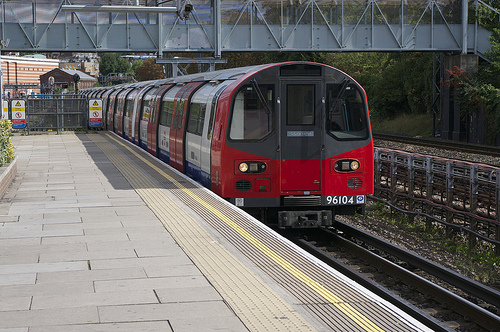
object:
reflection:
[104, 86, 228, 140]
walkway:
[0, 0, 500, 58]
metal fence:
[25, 93, 89, 135]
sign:
[88, 99, 102, 131]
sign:
[11, 99, 26, 128]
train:
[63, 60, 375, 230]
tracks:
[280, 133, 499, 332]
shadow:
[74, 123, 200, 191]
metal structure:
[0, 0, 500, 66]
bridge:
[0, 0, 500, 64]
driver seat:
[325, 99, 350, 132]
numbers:
[327, 195, 355, 205]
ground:
[0, 130, 432, 331]